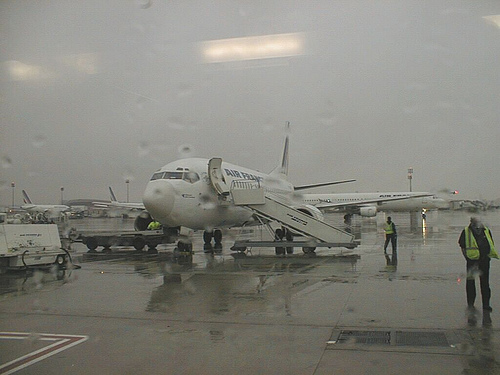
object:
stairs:
[229, 188, 358, 242]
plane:
[91, 119, 437, 254]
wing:
[316, 193, 434, 209]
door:
[207, 157, 230, 196]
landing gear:
[203, 228, 223, 244]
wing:
[92, 201, 146, 210]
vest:
[383, 221, 395, 235]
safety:
[464, 222, 500, 260]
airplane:
[302, 191, 450, 217]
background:
[1, 179, 500, 236]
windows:
[163, 171, 182, 179]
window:
[150, 172, 164, 180]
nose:
[142, 179, 176, 219]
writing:
[224, 168, 264, 182]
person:
[456, 210, 500, 312]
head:
[470, 214, 482, 228]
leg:
[479, 256, 492, 310]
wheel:
[213, 225, 225, 241]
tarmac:
[0, 200, 499, 374]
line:
[0, 330, 91, 375]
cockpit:
[148, 171, 201, 185]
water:
[178, 144, 194, 156]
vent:
[334, 330, 391, 345]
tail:
[267, 120, 291, 176]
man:
[381, 215, 398, 255]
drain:
[394, 332, 451, 347]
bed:
[80, 227, 164, 237]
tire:
[203, 230, 223, 243]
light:
[452, 190, 458, 194]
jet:
[20, 189, 70, 213]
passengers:
[29, 210, 39, 215]